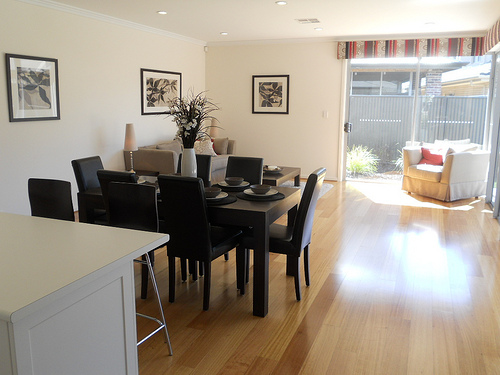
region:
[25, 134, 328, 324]
the table is black.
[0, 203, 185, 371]
the counter is white.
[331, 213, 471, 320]
light reflecting on the floor.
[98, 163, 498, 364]
the floor is wooden.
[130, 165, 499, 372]
the floor is brown.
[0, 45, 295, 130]
pictures hanging on the wall.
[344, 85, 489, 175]
the fence is wooden.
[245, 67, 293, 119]
the picture frame is black.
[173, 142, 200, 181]
the vase is white.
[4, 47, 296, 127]
three pictures on the wall.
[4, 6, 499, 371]
airy living and dining space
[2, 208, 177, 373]
white counter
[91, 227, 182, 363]
metal legs of object near counter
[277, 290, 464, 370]
hardwood floor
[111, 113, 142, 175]
narrow tabletop lamp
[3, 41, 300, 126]
three similar looking art pieces on wall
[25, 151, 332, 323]
a dark table and chairs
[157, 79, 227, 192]
large flower arrangement in a white vase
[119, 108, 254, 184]
a tan couch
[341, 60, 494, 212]
large cushioned chair in front of sliding doors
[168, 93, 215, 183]
Pretty flowers in a vase on the table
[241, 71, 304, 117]
Flower art hanging on the wall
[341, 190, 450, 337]
Shiny hardwood flooring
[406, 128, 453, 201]
Red pillow on a chair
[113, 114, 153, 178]
Lamp beside the sofa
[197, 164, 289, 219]
China setting on the table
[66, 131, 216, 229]
Contemporary dining set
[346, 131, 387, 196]
Plant in the yard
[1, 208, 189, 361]
White bar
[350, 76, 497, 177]
Fence dividing homes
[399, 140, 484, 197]
a white chair in the corner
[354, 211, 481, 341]
sunlight reflecting on a wood floor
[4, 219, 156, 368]
a white counter top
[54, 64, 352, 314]
a black dining table surrounded by black chair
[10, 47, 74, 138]
a black and white painting to the left of two other pictures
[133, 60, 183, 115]
a black and white picture between two others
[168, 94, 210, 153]
black and white flowers in a vase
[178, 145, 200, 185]
a tall white vase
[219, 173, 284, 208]
black dishes on a dining table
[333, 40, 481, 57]
a striped valance over windows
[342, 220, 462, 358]
the floor is wooden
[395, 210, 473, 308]
there is reflection on the floor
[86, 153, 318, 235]
the table is black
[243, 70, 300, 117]
the frame is blak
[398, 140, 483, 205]
the sofa is white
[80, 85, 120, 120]
the wall is clean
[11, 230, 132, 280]
the counter is white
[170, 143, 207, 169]
the vase is white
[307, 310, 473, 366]
the floor is gloosy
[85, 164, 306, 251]
the table is wooden